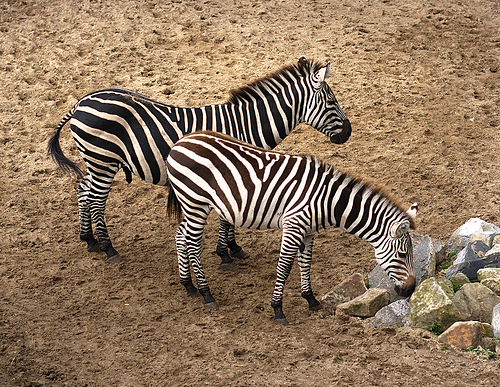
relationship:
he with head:
[166, 131, 418, 325] [370, 210, 419, 295]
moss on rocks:
[417, 267, 454, 321] [421, 212, 497, 346]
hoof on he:
[310, 302, 326, 311] [166, 131, 418, 325]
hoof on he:
[275, 313, 287, 325] [166, 131, 418, 325]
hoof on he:
[207, 299, 220, 311] [166, 131, 418, 325]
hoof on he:
[221, 258, 240, 271] [166, 131, 418, 325]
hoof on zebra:
[231, 245, 249, 258] [31, 41, 355, 263]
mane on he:
[336, 163, 415, 228] [166, 131, 418, 325]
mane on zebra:
[228, 55, 315, 102] [47, 54, 353, 260]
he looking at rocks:
[166, 128, 415, 321] [325, 214, 497, 347]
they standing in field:
[48, 53, 415, 328] [2, 0, 499, 385]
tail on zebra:
[43, 100, 91, 194] [47, 54, 353, 260]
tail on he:
[160, 177, 187, 222] [166, 131, 418, 325]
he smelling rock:
[166, 131, 418, 325] [366, 235, 437, 298]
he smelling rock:
[166, 131, 418, 325] [438, 317, 496, 349]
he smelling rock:
[166, 131, 418, 325] [451, 281, 498, 322]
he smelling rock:
[166, 131, 418, 325] [334, 285, 389, 317]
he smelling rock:
[166, 131, 418, 325] [321, 272, 370, 307]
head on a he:
[369, 195, 423, 296] [166, 131, 418, 325]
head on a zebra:
[294, 50, 355, 146] [47, 54, 353, 260]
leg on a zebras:
[269, 217, 312, 326] [26, 44, 439, 322]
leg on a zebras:
[292, 233, 324, 313] [26, 44, 439, 322]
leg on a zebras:
[176, 208, 188, 297] [26, 44, 439, 322]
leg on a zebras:
[178, 195, 216, 309] [26, 44, 439, 322]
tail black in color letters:
[46, 102, 86, 178] [44, 117, 84, 181]